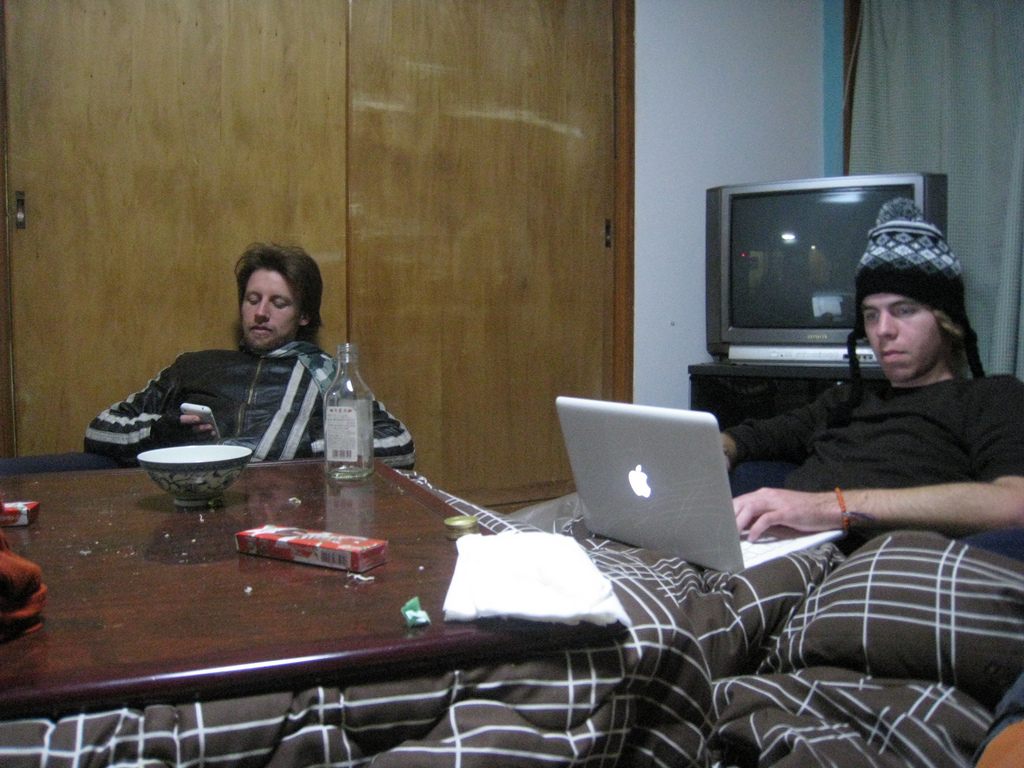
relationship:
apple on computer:
[623, 459, 661, 506] [541, 384, 844, 573]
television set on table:
[701, 170, 950, 369] [678, 357, 913, 418]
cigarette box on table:
[234, 515, 390, 579] [9, 446, 634, 721]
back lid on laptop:
[551, 390, 749, 576] [552, 388, 848, 572]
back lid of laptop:
[613, 472, 650, 507] [503, 386, 765, 598]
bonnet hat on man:
[842, 193, 993, 401] [847, 328, 1001, 462]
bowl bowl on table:
[124, 429, 259, 511] [108, 526, 404, 741]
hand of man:
[721, 469, 856, 576] [795, 197, 1010, 437]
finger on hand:
[733, 487, 783, 546] [728, 458, 860, 549]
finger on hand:
[732, 487, 754, 520] [711, 458, 837, 554]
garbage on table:
[376, 575, 454, 638] [19, 413, 650, 764]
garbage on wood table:
[421, 486, 474, 560] [21, 430, 521, 698]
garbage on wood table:
[339, 554, 387, 593] [30, 413, 525, 742]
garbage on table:
[222, 519, 430, 604] [0, 445, 635, 721]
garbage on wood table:
[225, 564, 310, 642] [30, 441, 666, 697]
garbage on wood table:
[4, 480, 48, 541] [36, 458, 620, 687]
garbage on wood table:
[60, 519, 113, 580] [15, 459, 515, 699]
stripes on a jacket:
[244, 359, 314, 446] [86, 346, 398, 470]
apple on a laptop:
[622, 458, 660, 505] [492, 353, 877, 624]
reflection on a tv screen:
[773, 217, 826, 263] [715, 147, 934, 409]